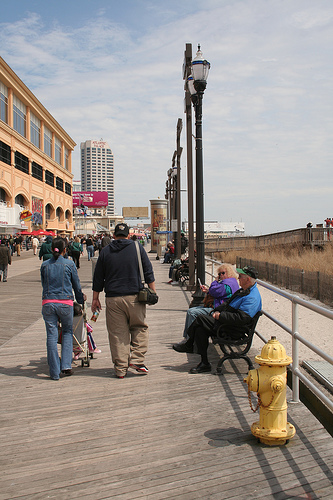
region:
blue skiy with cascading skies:
[95, 27, 130, 85]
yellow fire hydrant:
[251, 343, 312, 444]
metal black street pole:
[171, 55, 232, 206]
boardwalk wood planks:
[41, 408, 174, 474]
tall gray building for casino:
[82, 125, 145, 225]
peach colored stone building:
[9, 142, 66, 228]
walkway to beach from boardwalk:
[226, 211, 314, 246]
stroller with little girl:
[72, 304, 116, 370]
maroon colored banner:
[72, 181, 116, 227]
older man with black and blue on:
[232, 270, 248, 333]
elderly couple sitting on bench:
[199, 259, 270, 334]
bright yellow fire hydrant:
[247, 333, 292, 447]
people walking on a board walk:
[42, 202, 211, 445]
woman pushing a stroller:
[37, 233, 105, 370]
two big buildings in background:
[35, 102, 123, 246]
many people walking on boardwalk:
[16, 190, 117, 302]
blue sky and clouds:
[82, 56, 307, 221]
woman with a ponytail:
[31, 239, 72, 278]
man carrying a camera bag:
[117, 254, 165, 347]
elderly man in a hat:
[237, 259, 263, 289]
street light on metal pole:
[178, 44, 241, 235]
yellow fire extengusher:
[237, 329, 302, 458]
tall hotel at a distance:
[75, 129, 137, 225]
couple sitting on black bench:
[174, 253, 292, 404]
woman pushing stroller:
[33, 233, 96, 399]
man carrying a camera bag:
[92, 217, 163, 372]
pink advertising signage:
[68, 183, 118, 213]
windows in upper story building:
[7, 104, 93, 174]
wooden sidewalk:
[13, 377, 287, 498]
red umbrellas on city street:
[6, 223, 81, 242]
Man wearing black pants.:
[186, 320, 224, 379]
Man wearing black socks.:
[181, 333, 216, 391]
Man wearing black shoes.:
[171, 325, 207, 412]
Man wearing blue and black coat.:
[229, 291, 251, 352]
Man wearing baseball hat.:
[239, 266, 259, 281]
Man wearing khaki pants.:
[112, 319, 149, 352]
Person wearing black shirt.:
[112, 270, 140, 311]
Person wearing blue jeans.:
[44, 316, 72, 357]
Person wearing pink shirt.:
[33, 274, 93, 336]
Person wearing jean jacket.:
[32, 274, 97, 309]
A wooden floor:
[125, 444, 194, 497]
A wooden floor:
[144, 429, 171, 461]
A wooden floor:
[169, 431, 201, 475]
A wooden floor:
[177, 420, 224, 493]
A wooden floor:
[151, 414, 212, 493]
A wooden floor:
[108, 376, 185, 467]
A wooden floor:
[151, 446, 183, 476]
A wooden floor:
[157, 417, 177, 439]